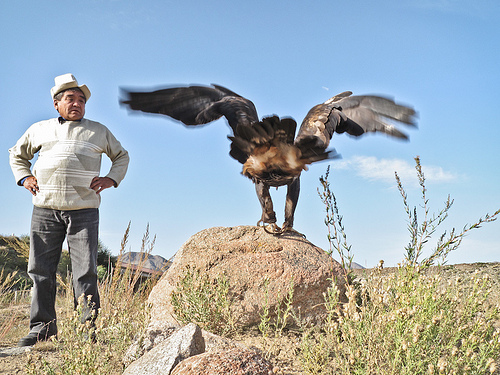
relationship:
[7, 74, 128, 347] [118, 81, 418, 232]
man watching bird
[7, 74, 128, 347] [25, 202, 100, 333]
man on jeans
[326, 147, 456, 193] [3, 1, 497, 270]
cloud in sky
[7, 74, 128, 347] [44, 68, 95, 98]
man wearing hat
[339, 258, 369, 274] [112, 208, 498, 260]
mountain in background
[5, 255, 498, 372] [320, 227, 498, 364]
field with plant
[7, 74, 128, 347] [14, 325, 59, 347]
man wearing shoe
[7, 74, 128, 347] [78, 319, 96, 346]
man wearing shoe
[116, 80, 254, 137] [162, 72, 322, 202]
left wing of bird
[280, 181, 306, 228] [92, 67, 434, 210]
right leg of bird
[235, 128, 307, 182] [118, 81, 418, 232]
bird body of bird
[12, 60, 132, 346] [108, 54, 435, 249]
man observing bird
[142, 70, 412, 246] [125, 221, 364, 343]
bird perched on rock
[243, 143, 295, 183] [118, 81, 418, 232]
face of bird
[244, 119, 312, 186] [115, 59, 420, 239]
tail feather of bird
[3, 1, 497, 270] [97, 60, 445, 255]
sky above bird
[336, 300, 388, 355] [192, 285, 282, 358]
grass with plants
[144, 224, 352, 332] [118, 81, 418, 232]
rock with bird